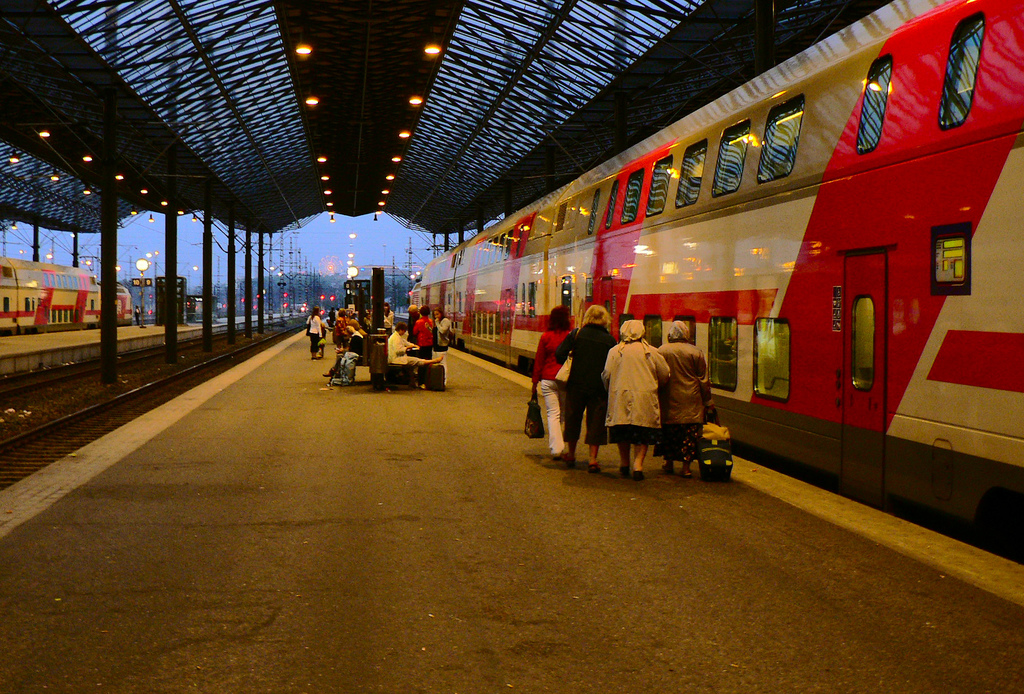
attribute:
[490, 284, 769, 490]
old women — old 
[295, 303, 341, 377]
person — black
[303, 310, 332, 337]
shirt — white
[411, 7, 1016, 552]
train — large, red, white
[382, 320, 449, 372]
person — sitting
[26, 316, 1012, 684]
platform — concrete, waiting